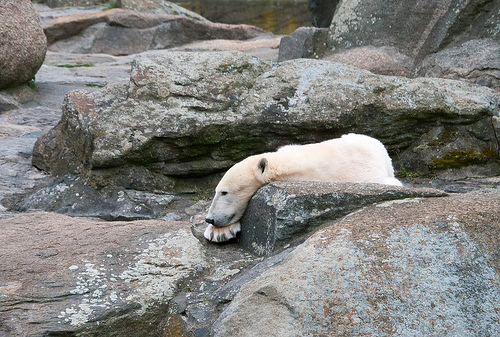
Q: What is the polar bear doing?
A: He is resting.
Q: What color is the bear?
A: The bear is white.